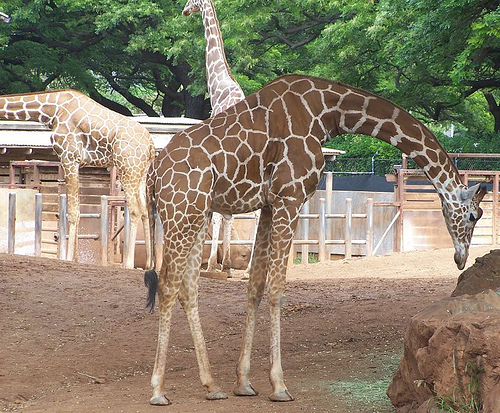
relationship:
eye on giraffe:
[466, 200, 482, 226] [117, 34, 484, 404]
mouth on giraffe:
[440, 235, 475, 279] [117, 34, 484, 404]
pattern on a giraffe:
[242, 104, 306, 160] [143, 85, 483, 385]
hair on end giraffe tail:
[141, 271, 158, 307] [140, 176, 160, 315]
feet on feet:
[265, 375, 295, 402] [255, 383, 303, 402]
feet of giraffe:
[255, 383, 303, 402] [115, 89, 484, 403]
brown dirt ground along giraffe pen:
[12, 272, 152, 413] [34, 204, 468, 254]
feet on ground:
[265, 375, 295, 402] [5, 233, 477, 410]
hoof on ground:
[230, 371, 256, 398] [5, 233, 477, 410]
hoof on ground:
[198, 375, 226, 395] [5, 233, 477, 410]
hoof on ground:
[142, 374, 192, 404] [5, 233, 477, 410]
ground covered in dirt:
[0, 253, 469, 399] [0, 260, 125, 366]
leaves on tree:
[375, 64, 412, 90] [10, 1, 484, 136]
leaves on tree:
[274, 54, 424, 77] [10, 1, 484, 136]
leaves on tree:
[168, 27, 198, 50] [81, 1, 483, 165]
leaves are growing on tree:
[472, 6, 496, 41] [434, 6, 498, 163]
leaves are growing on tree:
[66, 22, 166, 83] [22, 9, 203, 115]